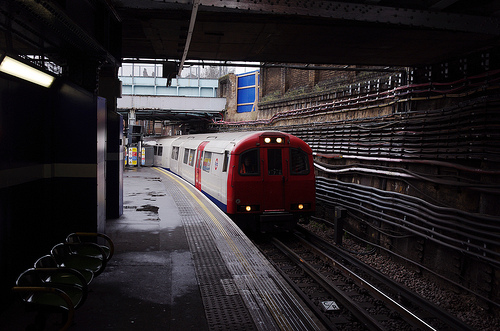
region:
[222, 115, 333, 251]
the lights on the front of the train are on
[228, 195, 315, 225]
the headlights are small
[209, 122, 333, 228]
the front of the train is red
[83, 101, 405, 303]
the train is in motion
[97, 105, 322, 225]
the train is coming into the station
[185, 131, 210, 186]
the doors are red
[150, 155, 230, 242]
a yellow line on the edge of the platform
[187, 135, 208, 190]
the doors are closed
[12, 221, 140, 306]
empty seats on the platform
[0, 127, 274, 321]
the seating area is dark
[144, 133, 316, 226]
a train is on the tracks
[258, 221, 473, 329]
a section of train tracks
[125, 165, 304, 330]
a metal and stone platform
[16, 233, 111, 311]
a row of metal chairs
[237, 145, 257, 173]
window on a train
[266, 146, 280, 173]
window on a train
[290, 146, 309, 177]
window on a train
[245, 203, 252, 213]
light on a train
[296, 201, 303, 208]
light on a train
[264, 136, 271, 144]
light on a train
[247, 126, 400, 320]
this is a train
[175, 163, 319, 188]
the train is red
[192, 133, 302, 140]
these are two lights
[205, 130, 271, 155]
this is a window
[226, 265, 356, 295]
these are some tracks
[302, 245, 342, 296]
the tracks are metal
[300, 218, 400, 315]
the tracks are rusted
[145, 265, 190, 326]
this is a platform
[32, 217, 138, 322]
these are some seats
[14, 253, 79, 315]
the seats are black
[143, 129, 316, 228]
grey and red train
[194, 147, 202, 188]
door panel on train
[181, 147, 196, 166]
windows on side of train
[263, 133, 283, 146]
top lights on train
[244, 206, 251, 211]
head light on train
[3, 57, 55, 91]
tube light on ceiling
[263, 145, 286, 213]
front door on train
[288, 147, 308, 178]
front window on train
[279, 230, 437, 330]
metal and wood train tracks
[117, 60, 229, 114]
blue and grey bridge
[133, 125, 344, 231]
a silver and red trail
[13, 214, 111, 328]
a row of black seats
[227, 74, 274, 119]
a blue portion of wall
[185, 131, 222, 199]
red doors on train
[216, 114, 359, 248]
red on front of train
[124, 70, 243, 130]
a bridge over the train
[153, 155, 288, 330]
yellow line on the ground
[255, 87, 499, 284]
wires along the wall